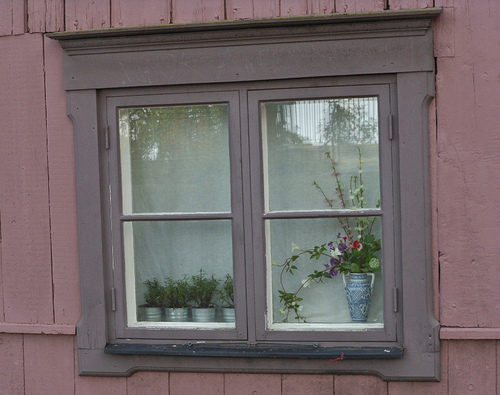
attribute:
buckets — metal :
[118, 293, 255, 334]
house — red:
[0, 1, 500, 390]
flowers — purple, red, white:
[281, 160, 380, 314]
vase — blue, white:
[341, 277, 378, 322]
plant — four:
[137, 279, 165, 322]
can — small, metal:
[142, 298, 245, 332]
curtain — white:
[148, 121, 236, 264]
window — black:
[105, 335, 411, 365]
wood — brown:
[48, 5, 441, 84]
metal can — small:
[221, 303, 234, 323]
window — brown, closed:
[66, 12, 453, 376]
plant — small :
[142, 277, 164, 320]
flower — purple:
[337, 240, 349, 255]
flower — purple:
[327, 253, 342, 266]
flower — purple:
[327, 265, 340, 278]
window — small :
[67, 54, 440, 374]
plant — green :
[302, 185, 384, 309]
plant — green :
[138, 277, 165, 324]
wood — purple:
[4, 5, 63, 393]